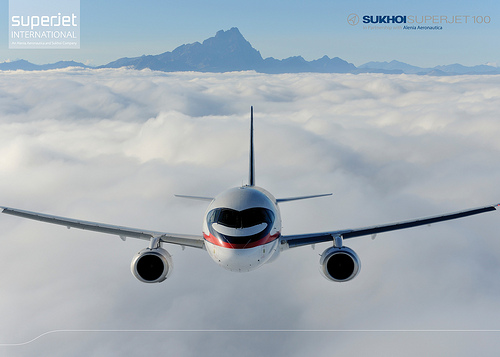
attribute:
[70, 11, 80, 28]
letter — white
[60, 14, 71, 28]
letter — white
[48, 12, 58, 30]
letter — white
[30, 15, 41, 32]
letter — white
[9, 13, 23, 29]
letter — white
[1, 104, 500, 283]
plane — white, large, in the air, flying, black, red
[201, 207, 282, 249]
front — black, red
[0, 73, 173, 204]
clouds — white, fluffy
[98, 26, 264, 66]
mountain — far away, high, in the background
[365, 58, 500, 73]
mountain — far away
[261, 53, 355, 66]
mountain — far away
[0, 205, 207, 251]
wing — long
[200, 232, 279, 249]
line — red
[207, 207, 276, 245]
line — black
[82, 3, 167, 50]
sky — blue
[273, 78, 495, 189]
clouds — white, these